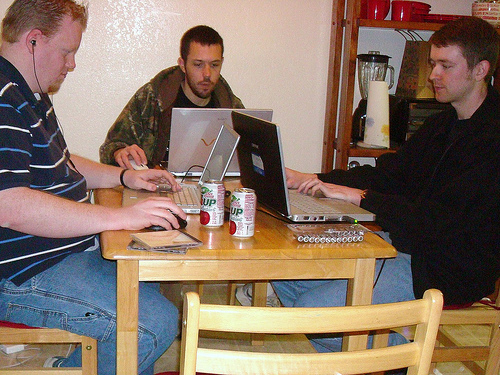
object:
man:
[0, 0, 188, 375]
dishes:
[412, 0, 472, 25]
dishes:
[390, 1, 412, 21]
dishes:
[359, 1, 389, 22]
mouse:
[128, 158, 149, 170]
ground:
[381, 120, 423, 162]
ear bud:
[30, 40, 82, 177]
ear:
[25, 29, 42, 54]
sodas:
[200, 179, 258, 239]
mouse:
[144, 210, 187, 231]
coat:
[313, 81, 499, 309]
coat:
[97, 65, 245, 169]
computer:
[157, 106, 275, 176]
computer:
[230, 110, 376, 224]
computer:
[119, 122, 240, 215]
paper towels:
[363, 81, 390, 149]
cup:
[361, 80, 390, 149]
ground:
[393, 187, 416, 208]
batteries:
[292, 233, 364, 244]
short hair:
[426, 15, 500, 80]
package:
[289, 223, 371, 245]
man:
[269, 16, 499, 375]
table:
[92, 177, 399, 375]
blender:
[351, 49, 396, 151]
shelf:
[320, 94, 397, 173]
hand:
[123, 196, 187, 232]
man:
[98, 23, 244, 171]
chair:
[178, 288, 445, 375]